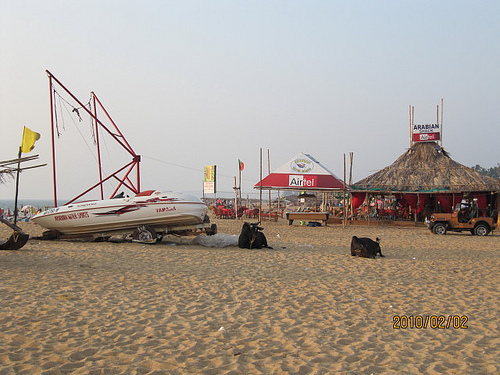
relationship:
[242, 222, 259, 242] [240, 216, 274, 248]
head of cow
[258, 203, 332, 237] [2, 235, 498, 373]
bench on beach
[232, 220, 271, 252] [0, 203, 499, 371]
motor on sand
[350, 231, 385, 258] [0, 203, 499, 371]
motor on sand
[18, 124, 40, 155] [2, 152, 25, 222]
flag on pole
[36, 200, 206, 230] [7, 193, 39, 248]
boat on trailer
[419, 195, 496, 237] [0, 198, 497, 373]
vehicle on beach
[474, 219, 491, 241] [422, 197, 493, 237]
wheel on vehicle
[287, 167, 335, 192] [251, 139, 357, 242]
sign on tent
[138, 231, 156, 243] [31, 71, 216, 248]
wheel on trailer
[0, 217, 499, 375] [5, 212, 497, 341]
bench on beach